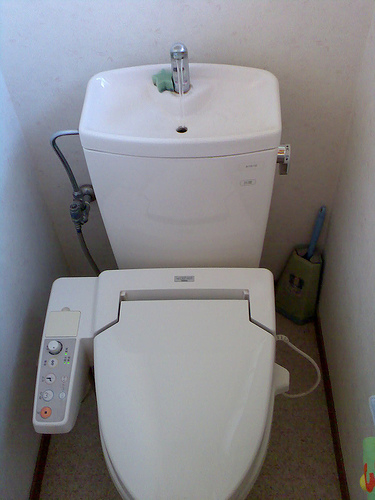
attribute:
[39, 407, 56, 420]
button — orange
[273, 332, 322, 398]
wire — white